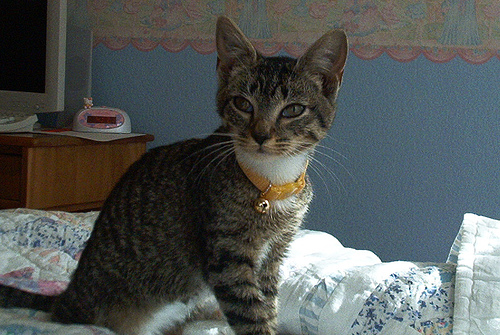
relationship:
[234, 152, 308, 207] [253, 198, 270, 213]
collar with bell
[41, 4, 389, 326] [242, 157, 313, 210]
cat wearing collar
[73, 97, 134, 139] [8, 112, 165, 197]
clock on nightstand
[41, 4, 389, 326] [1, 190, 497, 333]
cat on bed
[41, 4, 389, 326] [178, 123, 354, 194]
cat has whiskers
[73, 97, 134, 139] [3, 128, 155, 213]
clock on nightstand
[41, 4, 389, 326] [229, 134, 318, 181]
cat has neck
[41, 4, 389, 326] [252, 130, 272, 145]
cat has nose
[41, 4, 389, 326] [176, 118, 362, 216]
cat has whiskers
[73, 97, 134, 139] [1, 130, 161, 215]
clock on table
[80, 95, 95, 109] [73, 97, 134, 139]
hello kitty on clock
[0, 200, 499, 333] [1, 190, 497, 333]
blanket on bed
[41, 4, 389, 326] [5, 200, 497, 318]
cat sitting on bed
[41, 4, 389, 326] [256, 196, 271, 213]
cat wearing bell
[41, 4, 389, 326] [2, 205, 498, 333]
cat on bed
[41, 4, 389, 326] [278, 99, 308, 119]
cat has eye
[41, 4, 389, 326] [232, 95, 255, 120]
cat has eye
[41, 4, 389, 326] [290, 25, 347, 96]
cat has ear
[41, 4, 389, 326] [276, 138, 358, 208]
cat has whiskers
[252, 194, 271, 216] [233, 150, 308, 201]
bell on collar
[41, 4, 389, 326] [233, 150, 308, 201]
cat wearing collar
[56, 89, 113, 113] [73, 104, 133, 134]
figure on clock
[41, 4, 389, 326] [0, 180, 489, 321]
cat on quilt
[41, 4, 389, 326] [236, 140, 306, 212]
cat wearing collar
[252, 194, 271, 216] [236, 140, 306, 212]
bell hanging from collar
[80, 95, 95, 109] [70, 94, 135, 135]
hello kitty on clock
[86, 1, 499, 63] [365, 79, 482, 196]
picture on wall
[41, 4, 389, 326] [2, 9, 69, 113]
cat left of frame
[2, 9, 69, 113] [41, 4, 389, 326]
frame left of cat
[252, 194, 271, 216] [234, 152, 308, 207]
bell on collar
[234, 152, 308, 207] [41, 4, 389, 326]
collar on cat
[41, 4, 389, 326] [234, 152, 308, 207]
cat on collar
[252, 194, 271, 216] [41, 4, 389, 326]
bell on cat